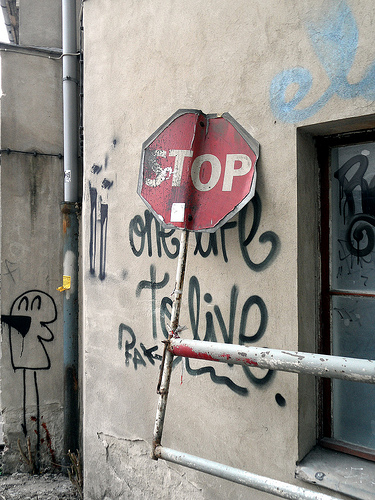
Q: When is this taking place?
A: Daytime.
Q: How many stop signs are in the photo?
A: One.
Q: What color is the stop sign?
A: Red and white.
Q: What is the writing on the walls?
A: Graffiti.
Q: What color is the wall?
A: Tan.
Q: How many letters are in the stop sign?
A: Four.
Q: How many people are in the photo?
A: None.